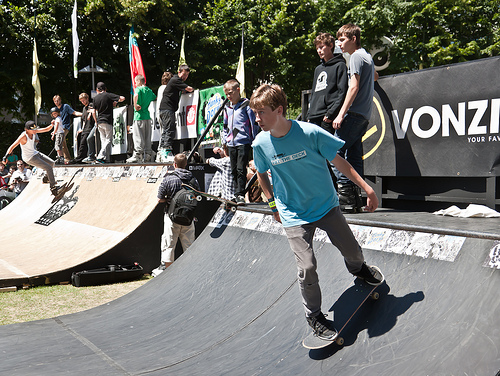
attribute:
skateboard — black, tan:
[316, 282, 373, 337]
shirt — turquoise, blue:
[269, 124, 336, 227]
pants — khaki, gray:
[279, 231, 382, 305]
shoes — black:
[303, 307, 330, 342]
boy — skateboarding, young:
[219, 84, 381, 303]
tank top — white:
[21, 135, 40, 165]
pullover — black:
[309, 58, 349, 106]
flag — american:
[60, 16, 93, 68]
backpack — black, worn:
[170, 188, 203, 225]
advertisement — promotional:
[390, 75, 497, 170]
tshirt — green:
[122, 89, 151, 118]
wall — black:
[387, 64, 463, 172]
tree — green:
[252, 16, 306, 81]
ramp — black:
[150, 263, 249, 347]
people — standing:
[48, 86, 178, 157]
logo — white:
[391, 100, 461, 140]